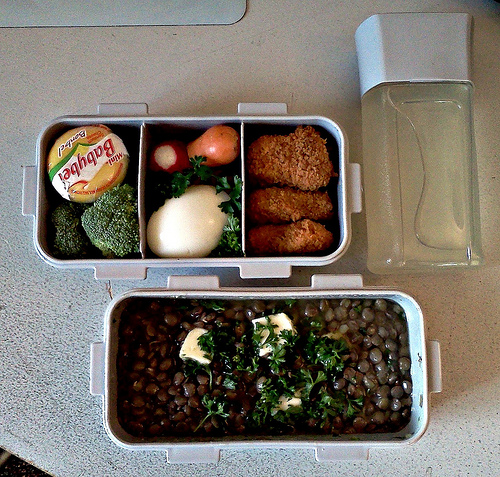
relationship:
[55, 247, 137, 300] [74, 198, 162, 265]
tray has broccoli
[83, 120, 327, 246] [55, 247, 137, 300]
food has tray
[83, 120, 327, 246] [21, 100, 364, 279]
food has container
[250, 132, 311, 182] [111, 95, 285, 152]
meat in container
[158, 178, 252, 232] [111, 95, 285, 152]
egg in container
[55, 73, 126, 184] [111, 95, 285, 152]
cheese in container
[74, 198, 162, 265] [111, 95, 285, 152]
broccoli in container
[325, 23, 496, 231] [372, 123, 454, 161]
container for water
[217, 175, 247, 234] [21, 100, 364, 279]
parsley in container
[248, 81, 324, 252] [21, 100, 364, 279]
nuggets in container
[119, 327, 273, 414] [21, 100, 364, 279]
lentils in container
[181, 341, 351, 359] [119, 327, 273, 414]
butter on lentils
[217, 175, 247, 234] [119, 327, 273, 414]
parsley over lentils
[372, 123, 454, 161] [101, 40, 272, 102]
water on table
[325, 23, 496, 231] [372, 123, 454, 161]
container of water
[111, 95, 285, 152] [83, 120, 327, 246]
container of food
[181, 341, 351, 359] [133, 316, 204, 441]
butter in beans